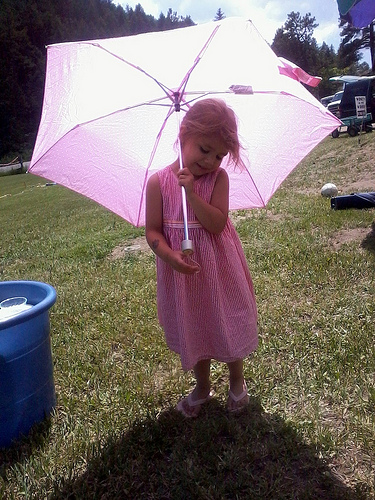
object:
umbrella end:
[42, 41, 57, 50]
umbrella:
[25, 14, 342, 226]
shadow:
[53, 392, 349, 500]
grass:
[352, 467, 374, 494]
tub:
[0, 283, 57, 444]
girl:
[147, 97, 254, 416]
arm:
[143, 177, 170, 259]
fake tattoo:
[152, 238, 159, 249]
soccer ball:
[320, 182, 338, 200]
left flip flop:
[227, 385, 251, 417]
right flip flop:
[176, 385, 211, 420]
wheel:
[347, 127, 360, 137]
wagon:
[332, 109, 373, 137]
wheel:
[365, 123, 373, 134]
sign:
[354, 94, 368, 121]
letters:
[358, 101, 360, 104]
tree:
[336, 0, 374, 76]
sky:
[185, 1, 374, 48]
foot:
[225, 379, 248, 415]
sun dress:
[156, 162, 257, 362]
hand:
[174, 249, 201, 277]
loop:
[186, 249, 202, 275]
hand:
[175, 168, 196, 191]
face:
[184, 132, 227, 177]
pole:
[176, 113, 189, 237]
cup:
[0, 296, 27, 308]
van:
[327, 73, 374, 119]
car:
[327, 91, 344, 120]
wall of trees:
[0, 2, 341, 170]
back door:
[329, 72, 360, 85]